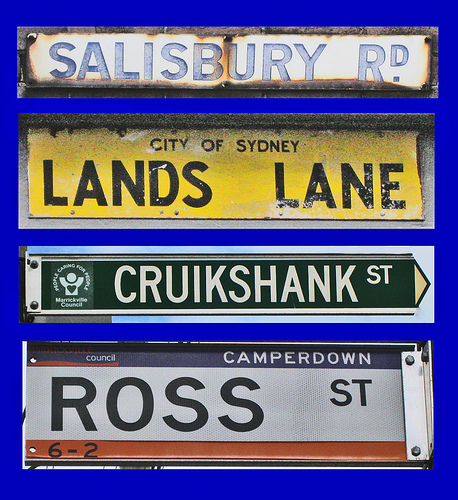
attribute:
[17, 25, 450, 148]
sign — rusty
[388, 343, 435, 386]
screw — silver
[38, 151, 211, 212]
word — LANDS 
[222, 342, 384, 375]
word — CAMPERDOWN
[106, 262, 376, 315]
word — CRUIKSHANK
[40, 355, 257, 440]
large letters — very large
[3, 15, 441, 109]
worn sign — worn 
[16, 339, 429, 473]
sign — red , blue , white 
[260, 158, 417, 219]
black letters — black 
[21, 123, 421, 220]
yellow sign — CITY OF SYDNEY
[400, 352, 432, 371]
silver screw — silver 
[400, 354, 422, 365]
silver screw — silver 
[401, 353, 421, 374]
silver screw — silver 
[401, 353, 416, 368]
silver screw — silver 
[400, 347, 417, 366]
silver screw — silver 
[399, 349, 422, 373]
silver screw — silver 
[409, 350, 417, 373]
silver screw — silver 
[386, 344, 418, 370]
silver screw — silver 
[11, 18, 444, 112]
sign — rusty , old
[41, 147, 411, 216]
lettering — fading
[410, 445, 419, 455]
screw — silver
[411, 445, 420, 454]
screw — silver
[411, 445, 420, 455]
screw — silver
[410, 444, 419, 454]
screw — silver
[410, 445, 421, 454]
screw — silver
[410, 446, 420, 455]
screw — silver